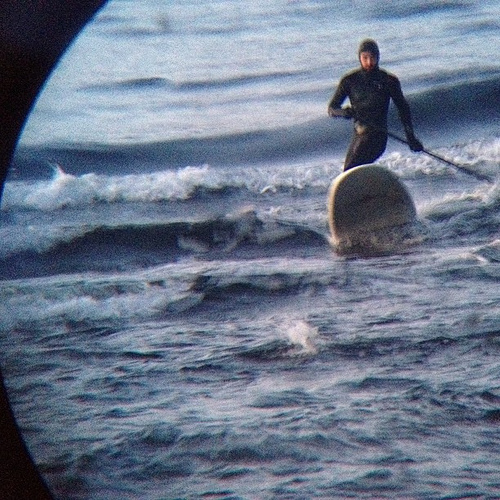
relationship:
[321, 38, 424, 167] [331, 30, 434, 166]
man wearing wet suit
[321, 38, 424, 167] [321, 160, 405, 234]
man on board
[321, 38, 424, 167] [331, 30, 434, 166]
man in wet suit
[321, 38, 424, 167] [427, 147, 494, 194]
man holding paddle